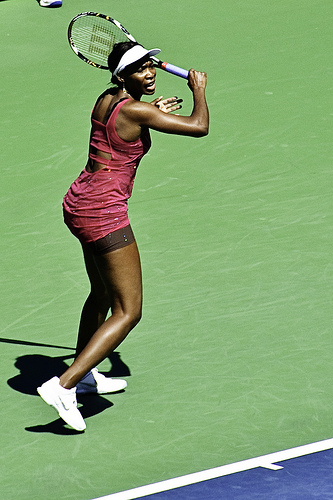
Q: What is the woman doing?
A: Playing tennis.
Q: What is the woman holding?
A: A racket.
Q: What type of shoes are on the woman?
A: Tennis shoes.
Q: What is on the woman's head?
A: A white visor.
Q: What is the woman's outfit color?
A: Pink.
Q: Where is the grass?
A: On the ground.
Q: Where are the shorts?
A: On the woman.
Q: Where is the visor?
A: On the woman.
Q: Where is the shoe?
A: On the woman.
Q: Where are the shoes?
A: On the woman.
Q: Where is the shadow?
A: On the ground.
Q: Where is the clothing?
A: On the woman.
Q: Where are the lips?
A: On the woman.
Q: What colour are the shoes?
A: White.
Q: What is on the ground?
A: Shadow.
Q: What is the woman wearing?
A: Tank top.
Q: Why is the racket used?
A: Play.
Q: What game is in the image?
A: Tennis.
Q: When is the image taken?
A: While playing.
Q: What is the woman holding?
A: Racket.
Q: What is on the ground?
A: Lines.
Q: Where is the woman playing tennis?
A: Court.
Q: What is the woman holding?
A: Racquet.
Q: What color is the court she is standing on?
A: Green.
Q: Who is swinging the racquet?
A: The tennis player.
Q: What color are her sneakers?
A: White.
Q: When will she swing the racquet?
A: When the ball is near.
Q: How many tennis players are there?
A: One.